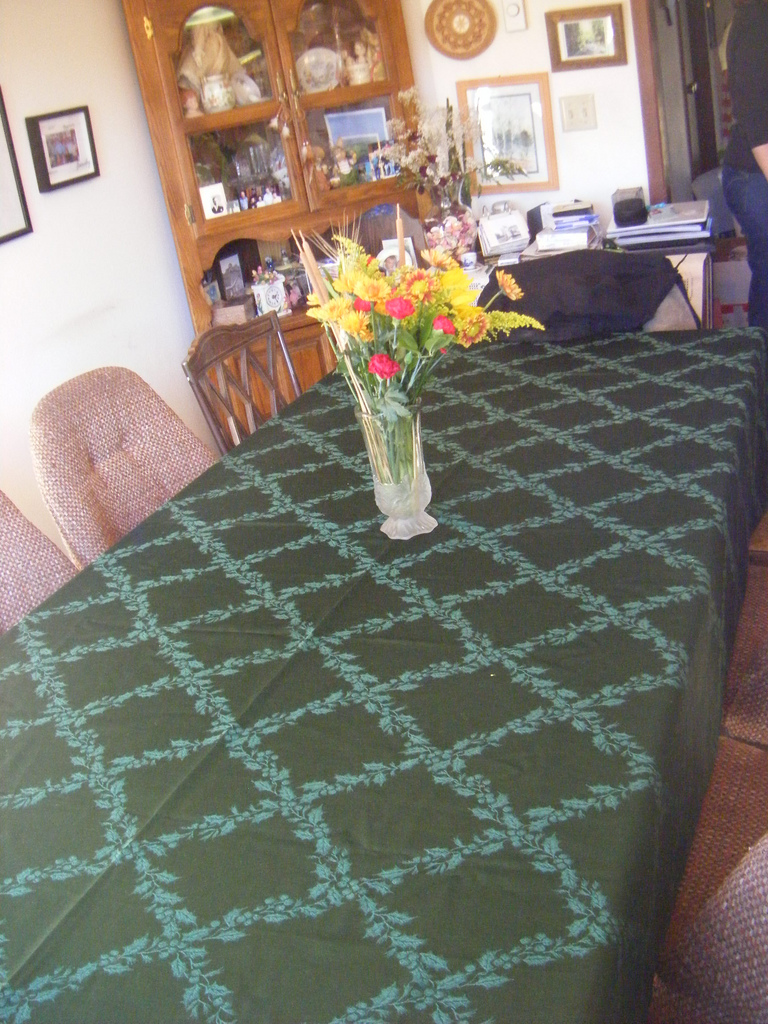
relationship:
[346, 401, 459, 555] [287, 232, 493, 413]
vase below flowers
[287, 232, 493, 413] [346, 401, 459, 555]
flowers above vase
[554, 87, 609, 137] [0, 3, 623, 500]
switches on wall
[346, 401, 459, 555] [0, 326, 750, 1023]
vase on top of cloth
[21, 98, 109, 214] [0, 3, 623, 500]
picture on wall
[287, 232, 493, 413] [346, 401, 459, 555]
flowers in vase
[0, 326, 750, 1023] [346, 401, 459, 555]
cloth below vase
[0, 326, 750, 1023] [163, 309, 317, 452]
cloth beside chair